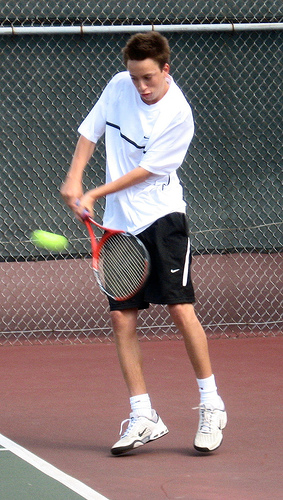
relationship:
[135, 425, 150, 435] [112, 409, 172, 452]
check on tennis shoe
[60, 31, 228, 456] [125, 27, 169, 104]
boy has head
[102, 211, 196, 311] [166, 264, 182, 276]
shorts has check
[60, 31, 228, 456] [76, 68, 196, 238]
boy wearing shirt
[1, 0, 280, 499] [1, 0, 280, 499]
court on court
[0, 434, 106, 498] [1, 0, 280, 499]
line on court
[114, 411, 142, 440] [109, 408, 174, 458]
laces are on sneakers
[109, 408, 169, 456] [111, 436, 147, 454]
shoe has edge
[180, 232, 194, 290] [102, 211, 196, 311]
line on shorts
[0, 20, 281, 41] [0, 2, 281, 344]
pole on fence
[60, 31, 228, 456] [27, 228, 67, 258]
boy swinging at ball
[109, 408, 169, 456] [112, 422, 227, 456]
shoe has trim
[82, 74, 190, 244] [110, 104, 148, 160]
shirt with stripe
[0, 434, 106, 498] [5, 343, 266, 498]
line of tennis court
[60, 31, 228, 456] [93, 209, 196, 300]
boy in shorts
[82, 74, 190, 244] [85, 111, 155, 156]
shirt with stripe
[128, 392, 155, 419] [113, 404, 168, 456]
sock and sneakers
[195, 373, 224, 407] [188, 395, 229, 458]
sock and sneakers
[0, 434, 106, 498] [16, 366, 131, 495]
line on court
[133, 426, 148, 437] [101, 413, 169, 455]
mark on shoe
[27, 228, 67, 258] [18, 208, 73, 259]
ball of ball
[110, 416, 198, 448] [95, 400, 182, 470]
side of sneaker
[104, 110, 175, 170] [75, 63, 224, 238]
stripe on shirt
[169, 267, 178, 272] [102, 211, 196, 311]
check mark on shorts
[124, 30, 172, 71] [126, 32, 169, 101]
hair on head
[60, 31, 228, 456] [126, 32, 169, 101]
boy has head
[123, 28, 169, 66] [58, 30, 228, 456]
spikey hair on boy